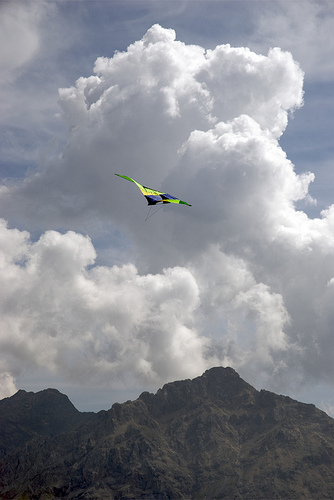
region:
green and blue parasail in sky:
[102, 163, 197, 229]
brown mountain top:
[188, 356, 252, 387]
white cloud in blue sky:
[31, 209, 168, 335]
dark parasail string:
[141, 202, 169, 231]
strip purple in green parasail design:
[145, 193, 179, 203]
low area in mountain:
[225, 414, 267, 449]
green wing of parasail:
[113, 170, 139, 188]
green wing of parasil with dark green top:
[162, 197, 198, 210]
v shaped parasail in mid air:
[109, 167, 189, 228]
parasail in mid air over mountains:
[75, 57, 283, 498]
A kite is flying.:
[93, 164, 223, 233]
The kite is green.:
[96, 160, 205, 220]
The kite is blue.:
[143, 186, 173, 205]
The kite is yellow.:
[138, 186, 162, 197]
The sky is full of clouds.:
[30, 18, 314, 198]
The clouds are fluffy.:
[39, 23, 313, 220]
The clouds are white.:
[27, 15, 314, 225]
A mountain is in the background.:
[1, 362, 333, 498]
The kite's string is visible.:
[54, 201, 165, 320]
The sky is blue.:
[10, 1, 270, 66]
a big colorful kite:
[111, 166, 203, 238]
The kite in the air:
[111, 168, 195, 208]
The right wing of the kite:
[161, 197, 197, 209]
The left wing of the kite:
[114, 171, 163, 194]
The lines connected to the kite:
[0, 204, 163, 404]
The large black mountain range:
[0, 364, 333, 499]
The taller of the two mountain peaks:
[108, 361, 332, 498]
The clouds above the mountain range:
[0, 0, 333, 417]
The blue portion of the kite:
[143, 191, 176, 205]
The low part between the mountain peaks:
[71, 399, 119, 421]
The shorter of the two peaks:
[0, 383, 78, 497]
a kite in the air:
[111, 178, 181, 235]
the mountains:
[7, 383, 317, 487]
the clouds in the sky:
[65, 266, 219, 345]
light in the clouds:
[130, 36, 274, 115]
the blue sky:
[57, 382, 118, 403]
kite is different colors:
[125, 172, 208, 230]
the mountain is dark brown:
[149, 379, 290, 457]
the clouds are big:
[205, 114, 332, 354]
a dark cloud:
[65, 326, 178, 390]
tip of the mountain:
[207, 358, 243, 373]